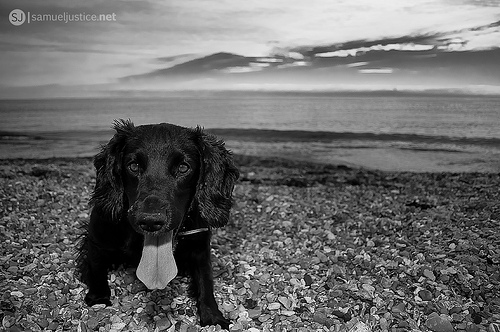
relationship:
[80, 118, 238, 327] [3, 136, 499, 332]
dog on beach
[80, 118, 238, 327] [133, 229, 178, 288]
dog has tongue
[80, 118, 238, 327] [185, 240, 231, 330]
dog has leg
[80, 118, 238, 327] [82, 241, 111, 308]
dog has leg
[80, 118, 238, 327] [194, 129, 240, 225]
dog has ear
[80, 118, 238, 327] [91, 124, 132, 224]
dog has ear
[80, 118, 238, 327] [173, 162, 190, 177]
dog has eye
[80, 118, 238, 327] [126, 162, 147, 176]
dog has eye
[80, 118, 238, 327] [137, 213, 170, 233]
dog has nose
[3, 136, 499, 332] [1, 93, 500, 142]
beach near water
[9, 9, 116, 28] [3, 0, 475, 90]
url in sky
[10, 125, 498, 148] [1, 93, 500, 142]
wave in water